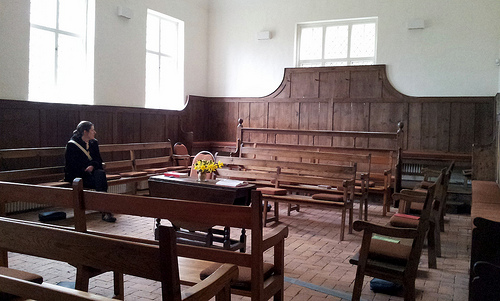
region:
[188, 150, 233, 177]
these are yellow flowers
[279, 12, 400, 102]
this is a window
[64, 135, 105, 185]
this is a black jacket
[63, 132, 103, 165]
this is a strap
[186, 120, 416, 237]
this is a bench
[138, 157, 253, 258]
this is a table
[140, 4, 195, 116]
this is a window frame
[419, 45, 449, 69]
this is the color white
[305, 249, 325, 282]
this is the color brown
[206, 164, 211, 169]
this is the color yellow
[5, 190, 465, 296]
a red brick floor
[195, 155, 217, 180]
yellow flowers on a table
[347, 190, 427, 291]
a wood chair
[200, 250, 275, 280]
a square cushion on a bench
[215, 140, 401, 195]
a wooden bench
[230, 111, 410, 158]
a wood railing behind a bench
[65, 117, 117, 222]
a woman in black seated on a bench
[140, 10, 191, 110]
a window in a room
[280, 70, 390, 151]
a wood covered wall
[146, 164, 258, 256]
a table in the center of a room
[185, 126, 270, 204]
Flowers on the table.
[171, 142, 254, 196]
Yellow flowers in a pot.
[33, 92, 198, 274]
Person sitting on a bench.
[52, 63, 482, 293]
Interior of a church.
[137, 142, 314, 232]
Table in the middle of the room.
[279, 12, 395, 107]
Window in the room.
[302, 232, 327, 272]
Tiles on the floor.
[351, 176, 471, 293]
Chairs with books on them.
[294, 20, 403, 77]
Lines on the window.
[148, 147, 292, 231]
Chair at the table.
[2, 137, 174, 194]
a long wooden bench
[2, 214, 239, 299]
a long wooden bench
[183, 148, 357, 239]
a long wooden bench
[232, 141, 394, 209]
a long wooden bench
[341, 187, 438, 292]
a long wooden bench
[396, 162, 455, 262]
a long wooden bench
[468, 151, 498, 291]
a long wooden bench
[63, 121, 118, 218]
woman sitting on bench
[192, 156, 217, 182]
vase of yellow flowers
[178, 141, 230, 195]
boquet of yellow flowers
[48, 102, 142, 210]
woman in black sitting on a bench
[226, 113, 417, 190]
long dark wooden bench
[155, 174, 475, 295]
brown tiled floor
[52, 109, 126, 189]
woman with dark brown hair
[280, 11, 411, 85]
three paned window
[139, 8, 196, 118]
large four paned window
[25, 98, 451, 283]
room full of benches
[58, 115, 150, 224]
woman sitting on a bench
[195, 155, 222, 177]
bright yellow flower petals